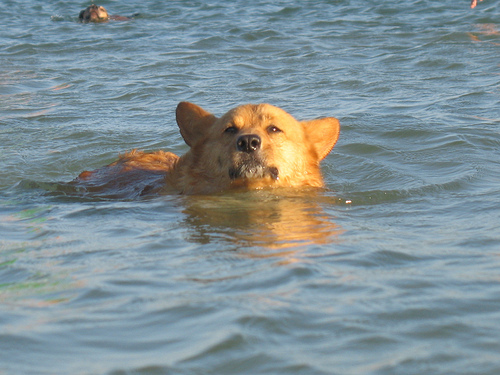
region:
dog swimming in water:
[55, 80, 347, 206]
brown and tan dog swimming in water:
[66, 2, 150, 37]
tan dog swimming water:
[62, 87, 351, 195]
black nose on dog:
[232, 132, 267, 156]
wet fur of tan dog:
[102, 144, 176, 177]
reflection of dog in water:
[177, 193, 354, 260]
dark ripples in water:
[198, 256, 370, 303]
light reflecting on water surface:
[4, 54, 78, 135]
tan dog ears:
[167, 94, 353, 161]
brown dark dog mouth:
[212, 153, 291, 190]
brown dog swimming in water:
[137, 82, 352, 209]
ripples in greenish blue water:
[36, 225, 157, 296]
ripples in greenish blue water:
[79, 261, 191, 351]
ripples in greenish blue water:
[162, 288, 273, 350]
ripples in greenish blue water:
[249, 219, 356, 327]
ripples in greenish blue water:
[362, 201, 442, 316]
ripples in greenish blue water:
[350, 46, 460, 137]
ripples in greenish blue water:
[0, 98, 67, 172]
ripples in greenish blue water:
[39, 52, 119, 100]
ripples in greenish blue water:
[190, 26, 268, 66]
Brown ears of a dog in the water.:
[173, 98, 340, 163]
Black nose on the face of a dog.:
[233, 131, 261, 152]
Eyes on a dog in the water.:
[220, 124, 282, 134]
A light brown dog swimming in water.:
[68, 96, 340, 194]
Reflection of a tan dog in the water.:
[182, 190, 342, 249]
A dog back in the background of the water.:
[77, 4, 112, 26]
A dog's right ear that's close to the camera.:
[176, 98, 215, 147]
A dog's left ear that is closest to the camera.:
[298, 114, 340, 164]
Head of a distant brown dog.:
[77, 4, 117, 24]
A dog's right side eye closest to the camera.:
[221, 123, 238, 134]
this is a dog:
[159, 108, 324, 173]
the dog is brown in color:
[278, 123, 309, 170]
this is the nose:
[241, 133, 262, 150]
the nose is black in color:
[238, 133, 255, 148]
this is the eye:
[261, 119, 285, 136]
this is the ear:
[301, 111, 348, 146]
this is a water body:
[363, 42, 493, 259]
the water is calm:
[378, 75, 478, 227]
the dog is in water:
[119, 110, 303, 252]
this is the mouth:
[233, 160, 275, 182]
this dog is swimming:
[55, 87, 439, 225]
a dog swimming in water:
[20, 77, 385, 229]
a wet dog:
[17, 83, 403, 228]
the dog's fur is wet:
[50, 65, 391, 235]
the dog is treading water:
[35, 67, 440, 257]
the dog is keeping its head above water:
[50, 66, 430, 241]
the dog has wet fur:
[31, 66, 397, 216]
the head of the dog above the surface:
[159, 60, 363, 204]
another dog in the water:
[65, 3, 139, 33]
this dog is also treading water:
[67, 2, 148, 39]